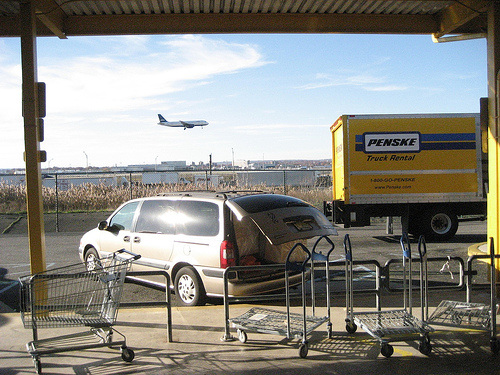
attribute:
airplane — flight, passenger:
[153, 112, 217, 135]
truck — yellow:
[313, 104, 498, 247]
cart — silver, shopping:
[11, 242, 155, 367]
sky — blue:
[0, 35, 498, 105]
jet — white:
[145, 104, 215, 136]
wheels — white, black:
[411, 205, 460, 245]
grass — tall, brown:
[4, 181, 332, 214]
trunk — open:
[233, 192, 330, 282]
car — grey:
[80, 191, 339, 301]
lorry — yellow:
[326, 110, 483, 244]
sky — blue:
[3, 34, 484, 175]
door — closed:
[96, 199, 139, 273]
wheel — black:
[121, 346, 136, 358]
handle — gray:
[27, 268, 173, 343]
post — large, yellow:
[18, 13, 47, 324]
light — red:
[218, 240, 236, 269]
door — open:
[224, 192, 336, 287]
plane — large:
[154, 111, 208, 132]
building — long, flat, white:
[136, 159, 214, 180]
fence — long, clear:
[5, 168, 315, 218]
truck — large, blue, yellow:
[332, 110, 483, 239]